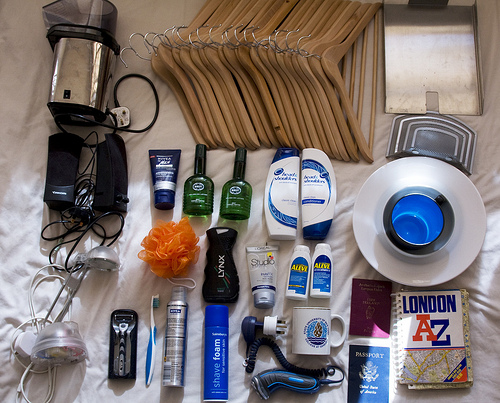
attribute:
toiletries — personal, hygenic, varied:
[138, 134, 299, 401]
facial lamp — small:
[7, 245, 119, 402]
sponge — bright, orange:
[142, 222, 203, 291]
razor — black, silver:
[107, 308, 138, 381]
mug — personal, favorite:
[293, 307, 344, 354]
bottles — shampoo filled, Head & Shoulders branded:
[263, 145, 298, 242]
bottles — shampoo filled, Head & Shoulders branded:
[298, 146, 338, 240]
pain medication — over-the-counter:
[311, 242, 333, 299]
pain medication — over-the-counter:
[285, 243, 308, 299]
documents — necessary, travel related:
[346, 276, 393, 401]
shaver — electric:
[249, 367, 325, 401]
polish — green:
[175, 134, 227, 221]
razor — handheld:
[108, 310, 140, 375]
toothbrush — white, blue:
[119, 274, 178, 392]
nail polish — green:
[219, 144, 256, 222]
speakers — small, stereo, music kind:
[39, 130, 138, 221]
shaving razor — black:
[105, 307, 140, 384]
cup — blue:
[399, 164, 447, 239]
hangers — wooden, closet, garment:
[116, 0, 383, 162]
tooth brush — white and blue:
[140, 294, 162, 388]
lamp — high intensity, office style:
[30, 221, 156, 383]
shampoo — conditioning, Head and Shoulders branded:
[265, 140, 337, 239]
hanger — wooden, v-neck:
[298, 0, 373, 160]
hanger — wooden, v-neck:
[283, 2, 368, 164]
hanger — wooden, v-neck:
[274, 2, 358, 162]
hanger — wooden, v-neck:
[267, 0, 347, 162]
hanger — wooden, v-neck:
[250, 2, 332, 157]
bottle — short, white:
[287, 245, 311, 297]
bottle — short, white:
[311, 245, 335, 297]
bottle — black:
[201, 225, 240, 307]